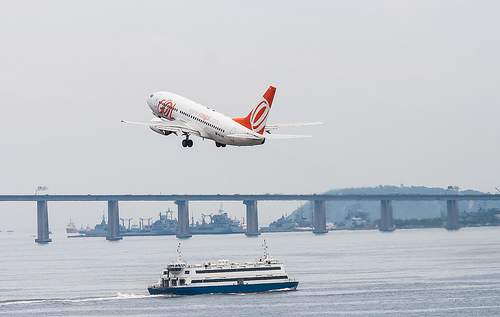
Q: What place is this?
A: It is a river.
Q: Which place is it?
A: It is a river.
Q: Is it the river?
A: Yes, it is the river.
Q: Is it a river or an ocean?
A: It is a river.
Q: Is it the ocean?
A: No, it is the river.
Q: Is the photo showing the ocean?
A: No, the picture is showing the river.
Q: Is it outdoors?
A: Yes, it is outdoors.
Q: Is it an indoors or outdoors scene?
A: It is outdoors.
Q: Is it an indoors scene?
A: No, it is outdoors.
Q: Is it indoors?
A: No, it is outdoors.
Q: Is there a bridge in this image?
A: Yes, there is a bridge.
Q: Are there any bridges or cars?
A: Yes, there is a bridge.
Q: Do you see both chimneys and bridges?
A: No, there is a bridge but no chimneys.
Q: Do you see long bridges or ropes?
A: Yes, there is a long bridge.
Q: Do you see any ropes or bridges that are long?
A: Yes, the bridge is long.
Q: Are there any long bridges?
A: Yes, there is a long bridge.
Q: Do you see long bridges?
A: Yes, there is a long bridge.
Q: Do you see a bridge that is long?
A: Yes, there is a long bridge.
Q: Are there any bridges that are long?
A: Yes, there is a bridge that is long.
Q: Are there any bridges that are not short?
A: Yes, there is a long bridge.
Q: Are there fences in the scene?
A: No, there are no fences.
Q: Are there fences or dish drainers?
A: No, there are no fences or dish drainers.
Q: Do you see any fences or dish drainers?
A: No, there are no fences or dish drainers.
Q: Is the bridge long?
A: Yes, the bridge is long.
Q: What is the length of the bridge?
A: The bridge is long.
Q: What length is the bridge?
A: The bridge is long.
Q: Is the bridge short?
A: No, the bridge is long.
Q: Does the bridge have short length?
A: No, the bridge is long.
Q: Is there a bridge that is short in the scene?
A: No, there is a bridge but it is long.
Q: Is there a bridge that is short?
A: No, there is a bridge but it is long.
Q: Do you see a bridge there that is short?
A: No, there is a bridge but it is long.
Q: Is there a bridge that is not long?
A: No, there is a bridge but it is long.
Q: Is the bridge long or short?
A: The bridge is long.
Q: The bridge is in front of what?
A: The bridge is in front of the hill.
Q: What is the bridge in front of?
A: The bridge is in front of the hill.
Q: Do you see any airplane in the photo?
A: Yes, there is an airplane.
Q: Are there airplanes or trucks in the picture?
A: Yes, there is an airplane.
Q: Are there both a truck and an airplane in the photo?
A: No, there is an airplane but no trucks.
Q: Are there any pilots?
A: No, there are no pilots.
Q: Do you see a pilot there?
A: No, there are no pilots.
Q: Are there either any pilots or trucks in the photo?
A: No, there are no pilots or trucks.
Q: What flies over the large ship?
A: The airplane flies over the ship.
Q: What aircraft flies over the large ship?
A: The aircraft is an airplane.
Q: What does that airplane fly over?
A: The airplane flies over the ship.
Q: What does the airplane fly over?
A: The airplane flies over the ship.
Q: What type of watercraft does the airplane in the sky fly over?
A: The plane flies over the ship.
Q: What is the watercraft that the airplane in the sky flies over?
A: The watercraft is a ship.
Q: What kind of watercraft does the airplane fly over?
A: The plane flies over the ship.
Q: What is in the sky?
A: The airplane is in the sky.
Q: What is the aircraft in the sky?
A: The aircraft is an airplane.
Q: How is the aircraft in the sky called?
A: The aircraft is an airplane.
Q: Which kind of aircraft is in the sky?
A: The aircraft is an airplane.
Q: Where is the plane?
A: The plane is in the sky.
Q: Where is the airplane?
A: The plane is in the sky.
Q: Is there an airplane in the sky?
A: Yes, there is an airplane in the sky.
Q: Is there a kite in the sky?
A: No, there is an airplane in the sky.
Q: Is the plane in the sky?
A: Yes, the plane is in the sky.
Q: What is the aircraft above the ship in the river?
A: The aircraft is an airplane.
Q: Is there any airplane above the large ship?
A: Yes, there is an airplane above the ship.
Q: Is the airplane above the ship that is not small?
A: Yes, the airplane is above the ship.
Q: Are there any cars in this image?
A: No, there are no cars.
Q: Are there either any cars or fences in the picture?
A: No, there are no cars or fences.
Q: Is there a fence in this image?
A: No, there are no fences.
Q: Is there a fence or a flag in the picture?
A: No, there are no fences or flags.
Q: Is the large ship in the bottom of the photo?
A: Yes, the ship is in the bottom of the image.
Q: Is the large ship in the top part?
A: No, the ship is in the bottom of the image.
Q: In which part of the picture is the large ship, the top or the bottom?
A: The ship is in the bottom of the image.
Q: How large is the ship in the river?
A: The ship is large.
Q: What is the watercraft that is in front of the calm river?
A: The watercraft is a ship.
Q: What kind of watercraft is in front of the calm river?
A: The watercraft is a ship.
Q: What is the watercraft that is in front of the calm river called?
A: The watercraft is a ship.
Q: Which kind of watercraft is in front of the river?
A: The watercraft is a ship.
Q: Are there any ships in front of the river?
A: Yes, there is a ship in front of the river.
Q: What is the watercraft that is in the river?
A: The watercraft is a ship.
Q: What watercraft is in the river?
A: The watercraft is a ship.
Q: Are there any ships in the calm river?
A: Yes, there is a ship in the river.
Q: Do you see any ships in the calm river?
A: Yes, there is a ship in the river.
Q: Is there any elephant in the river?
A: No, there is a ship in the river.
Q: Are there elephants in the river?
A: No, there is a ship in the river.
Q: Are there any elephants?
A: No, there are no elephants.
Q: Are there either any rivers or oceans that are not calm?
A: No, there is a river but it is calm.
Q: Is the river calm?
A: Yes, the river is calm.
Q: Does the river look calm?
A: Yes, the river is calm.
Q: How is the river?
A: The river is calm.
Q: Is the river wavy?
A: No, the river is calm.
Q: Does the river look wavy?
A: No, the river is calm.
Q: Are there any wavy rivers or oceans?
A: No, there is a river but it is calm.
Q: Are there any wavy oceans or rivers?
A: No, there is a river but it is calm.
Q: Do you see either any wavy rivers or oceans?
A: No, there is a river but it is calm.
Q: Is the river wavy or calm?
A: The river is calm.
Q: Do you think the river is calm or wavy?
A: The river is calm.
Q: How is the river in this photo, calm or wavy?
A: The river is calm.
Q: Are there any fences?
A: No, there are no fences.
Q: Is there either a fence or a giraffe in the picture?
A: No, there are no fences or giraffes.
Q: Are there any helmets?
A: No, there are no helmets.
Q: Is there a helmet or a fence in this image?
A: No, there are no helmets or fences.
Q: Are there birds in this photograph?
A: No, there are no birds.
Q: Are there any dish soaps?
A: No, there are no dish soaps.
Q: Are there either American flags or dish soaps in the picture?
A: No, there are no dish soaps or American flags.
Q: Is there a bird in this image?
A: No, there are no birds.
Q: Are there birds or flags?
A: No, there are no birds or flags.